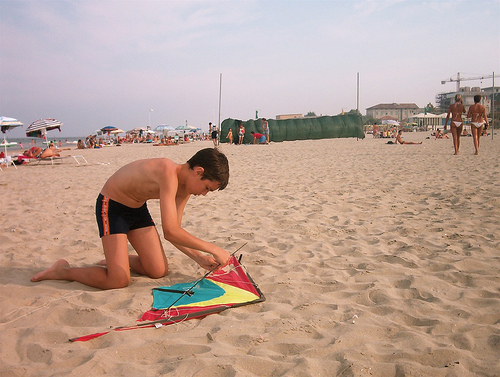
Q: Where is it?
A: This is at the beach.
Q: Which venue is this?
A: This is a beach.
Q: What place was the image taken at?
A: It was taken at the beach.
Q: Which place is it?
A: It is a beach.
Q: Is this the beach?
A: Yes, it is the beach.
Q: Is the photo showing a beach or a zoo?
A: It is showing a beach.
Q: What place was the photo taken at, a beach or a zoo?
A: It was taken at a beach.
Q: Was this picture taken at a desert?
A: No, the picture was taken in a beach.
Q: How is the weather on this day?
A: It is clear.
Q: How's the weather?
A: It is clear.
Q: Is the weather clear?
A: Yes, it is clear.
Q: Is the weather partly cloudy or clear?
A: It is clear.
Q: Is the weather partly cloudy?
A: No, it is clear.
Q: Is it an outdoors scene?
A: Yes, it is outdoors.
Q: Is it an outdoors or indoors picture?
A: It is outdoors.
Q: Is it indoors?
A: No, it is outdoors.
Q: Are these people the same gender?
A: No, they are both male and female.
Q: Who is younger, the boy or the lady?
A: The boy is younger than the lady.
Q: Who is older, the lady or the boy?
A: The lady is older than the boy.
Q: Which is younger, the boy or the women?
A: The boy is younger than the women.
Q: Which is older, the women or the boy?
A: The women is older than the boy.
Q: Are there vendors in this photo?
A: No, there are no vendors.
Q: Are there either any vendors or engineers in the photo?
A: No, there are no vendors or engineers.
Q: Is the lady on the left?
A: Yes, the lady is on the left of the image.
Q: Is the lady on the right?
A: No, the lady is on the left of the image.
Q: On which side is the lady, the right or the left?
A: The lady is on the left of the image.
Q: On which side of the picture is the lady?
A: The lady is on the left of the image.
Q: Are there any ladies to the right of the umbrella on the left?
A: Yes, there is a lady to the right of the umbrella.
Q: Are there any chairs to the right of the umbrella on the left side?
A: No, there is a lady to the right of the umbrella.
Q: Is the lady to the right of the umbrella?
A: Yes, the lady is to the right of the umbrella.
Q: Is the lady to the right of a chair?
A: No, the lady is to the right of the umbrella.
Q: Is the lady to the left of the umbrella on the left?
A: No, the lady is to the right of the umbrella.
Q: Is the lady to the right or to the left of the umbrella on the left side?
A: The lady is to the right of the umbrella.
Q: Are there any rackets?
A: No, there are no rackets.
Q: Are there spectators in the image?
A: No, there are no spectators.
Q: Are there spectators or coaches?
A: No, there are no spectators or coaches.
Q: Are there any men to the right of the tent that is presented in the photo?
A: Yes, there is a man to the right of the tent.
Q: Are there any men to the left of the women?
A: Yes, there is a man to the left of the women.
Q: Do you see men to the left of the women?
A: Yes, there is a man to the left of the women.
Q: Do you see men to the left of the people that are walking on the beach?
A: Yes, there is a man to the left of the women.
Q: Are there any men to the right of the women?
A: No, the man is to the left of the women.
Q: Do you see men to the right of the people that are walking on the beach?
A: No, the man is to the left of the women.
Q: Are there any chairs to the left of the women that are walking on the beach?
A: No, there is a man to the left of the women.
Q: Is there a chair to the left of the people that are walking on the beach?
A: No, there is a man to the left of the women.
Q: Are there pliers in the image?
A: No, there are no pliers.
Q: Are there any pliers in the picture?
A: No, there are no pliers.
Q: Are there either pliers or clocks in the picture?
A: No, there are no pliers or clocks.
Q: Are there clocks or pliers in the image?
A: No, there are no pliers or clocks.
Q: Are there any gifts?
A: No, there are no gifts.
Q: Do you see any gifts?
A: No, there are no gifts.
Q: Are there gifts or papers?
A: No, there are no gifts or papers.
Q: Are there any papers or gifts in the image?
A: No, there are no gifts or papers.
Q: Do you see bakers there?
A: No, there are no bakers.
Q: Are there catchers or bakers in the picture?
A: No, there are no bakers or catchers.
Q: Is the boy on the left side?
A: Yes, the boy is on the left of the image.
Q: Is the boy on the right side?
A: No, the boy is on the left of the image.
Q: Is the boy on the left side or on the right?
A: The boy is on the left of the image.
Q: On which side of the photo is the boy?
A: The boy is on the left of the image.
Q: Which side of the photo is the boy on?
A: The boy is on the left of the image.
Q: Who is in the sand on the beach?
A: The boy is in the sand.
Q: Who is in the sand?
A: The boy is in the sand.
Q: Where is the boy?
A: The boy is in the sand.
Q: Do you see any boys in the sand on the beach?
A: Yes, there is a boy in the sand.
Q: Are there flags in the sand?
A: No, there is a boy in the sand.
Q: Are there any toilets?
A: No, there are no toilets.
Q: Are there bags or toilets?
A: No, there are no toilets or bags.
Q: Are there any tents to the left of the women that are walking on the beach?
A: Yes, there is a tent to the left of the women.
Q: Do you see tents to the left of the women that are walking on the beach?
A: Yes, there is a tent to the left of the women.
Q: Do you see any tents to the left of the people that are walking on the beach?
A: Yes, there is a tent to the left of the women.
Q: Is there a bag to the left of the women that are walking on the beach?
A: No, there is a tent to the left of the women.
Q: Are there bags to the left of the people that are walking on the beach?
A: No, there is a tent to the left of the women.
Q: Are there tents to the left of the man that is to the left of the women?
A: Yes, there is a tent to the left of the man.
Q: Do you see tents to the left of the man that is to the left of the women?
A: Yes, there is a tent to the left of the man.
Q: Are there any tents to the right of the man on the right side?
A: No, the tent is to the left of the man.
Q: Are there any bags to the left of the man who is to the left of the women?
A: No, there is a tent to the left of the man.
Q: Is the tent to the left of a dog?
A: No, the tent is to the left of the man.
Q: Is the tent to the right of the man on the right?
A: No, the tent is to the left of the man.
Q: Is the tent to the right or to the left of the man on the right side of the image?
A: The tent is to the left of the man.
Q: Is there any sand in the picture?
A: Yes, there is sand.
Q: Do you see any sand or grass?
A: Yes, there is sand.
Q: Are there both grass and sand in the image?
A: No, there is sand but no grass.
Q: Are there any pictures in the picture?
A: No, there are no pictures.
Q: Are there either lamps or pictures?
A: No, there are no pictures or lamps.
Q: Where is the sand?
A: The sand is on the beach.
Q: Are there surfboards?
A: No, there are no surfboards.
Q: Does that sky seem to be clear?
A: Yes, the sky is clear.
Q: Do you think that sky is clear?
A: Yes, the sky is clear.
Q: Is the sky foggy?
A: No, the sky is clear.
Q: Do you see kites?
A: Yes, there is a kite.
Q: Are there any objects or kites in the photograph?
A: Yes, there is a kite.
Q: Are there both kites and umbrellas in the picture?
A: Yes, there are both a kite and umbrellas.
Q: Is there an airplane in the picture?
A: No, there are no airplanes.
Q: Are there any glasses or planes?
A: No, there are no planes or glasses.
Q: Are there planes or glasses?
A: No, there are no planes or glasses.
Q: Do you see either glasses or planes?
A: No, there are no planes or glasses.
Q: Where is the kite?
A: The kite is on the ground.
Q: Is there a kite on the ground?
A: Yes, there is a kite on the ground.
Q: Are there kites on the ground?
A: Yes, there is a kite on the ground.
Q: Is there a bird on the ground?
A: No, there is a kite on the ground.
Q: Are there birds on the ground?
A: No, there is a kite on the ground.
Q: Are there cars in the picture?
A: No, there are no cars.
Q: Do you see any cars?
A: No, there are no cars.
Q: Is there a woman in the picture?
A: Yes, there are women.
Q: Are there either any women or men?
A: Yes, there are women.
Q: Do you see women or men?
A: Yes, there are women.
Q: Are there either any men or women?
A: Yes, there are women.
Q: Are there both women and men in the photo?
A: Yes, there are both women and a man.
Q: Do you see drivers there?
A: No, there are no drivers.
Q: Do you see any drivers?
A: No, there are no drivers.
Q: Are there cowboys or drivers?
A: No, there are no drivers or cowboys.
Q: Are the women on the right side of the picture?
A: Yes, the women are on the right of the image.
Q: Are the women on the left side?
A: No, the women are on the right of the image.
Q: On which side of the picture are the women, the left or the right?
A: The women are on the right of the image.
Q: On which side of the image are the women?
A: The women are on the right of the image.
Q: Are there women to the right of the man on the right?
A: Yes, there are women to the right of the man.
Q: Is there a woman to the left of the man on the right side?
A: No, the women are to the right of the man.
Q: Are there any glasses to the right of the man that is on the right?
A: No, there are women to the right of the man.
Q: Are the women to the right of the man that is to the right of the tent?
A: Yes, the women are to the right of the man.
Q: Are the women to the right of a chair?
A: No, the women are to the right of the man.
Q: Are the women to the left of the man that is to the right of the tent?
A: No, the women are to the right of the man.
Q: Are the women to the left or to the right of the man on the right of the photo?
A: The women are to the right of the man.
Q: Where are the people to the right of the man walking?
A: The women are walking on the beach.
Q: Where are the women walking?
A: The women are walking on the beach.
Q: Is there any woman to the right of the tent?
A: Yes, there are women to the right of the tent.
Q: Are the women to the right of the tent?
A: Yes, the women are to the right of the tent.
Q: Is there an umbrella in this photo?
A: Yes, there is an umbrella.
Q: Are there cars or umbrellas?
A: Yes, there is an umbrella.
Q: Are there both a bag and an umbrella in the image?
A: No, there is an umbrella but no bags.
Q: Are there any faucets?
A: No, there are no faucets.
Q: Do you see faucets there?
A: No, there are no faucets.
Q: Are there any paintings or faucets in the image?
A: No, there are no faucets or paintings.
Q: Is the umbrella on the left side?
A: Yes, the umbrella is on the left of the image.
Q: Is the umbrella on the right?
A: No, the umbrella is on the left of the image.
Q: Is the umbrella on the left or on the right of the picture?
A: The umbrella is on the left of the image.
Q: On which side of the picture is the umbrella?
A: The umbrella is on the left of the image.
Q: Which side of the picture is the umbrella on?
A: The umbrella is on the left of the image.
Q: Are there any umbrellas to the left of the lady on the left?
A: Yes, there is an umbrella to the left of the lady.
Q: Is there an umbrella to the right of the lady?
A: No, the umbrella is to the left of the lady.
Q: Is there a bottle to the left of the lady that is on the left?
A: No, there is an umbrella to the left of the lady.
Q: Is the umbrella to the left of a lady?
A: Yes, the umbrella is to the left of a lady.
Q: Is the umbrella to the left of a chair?
A: No, the umbrella is to the left of a lady.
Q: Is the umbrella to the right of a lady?
A: No, the umbrella is to the left of a lady.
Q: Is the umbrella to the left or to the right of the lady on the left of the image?
A: The umbrella is to the left of the lady.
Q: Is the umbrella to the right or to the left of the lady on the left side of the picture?
A: The umbrella is to the left of the lady.